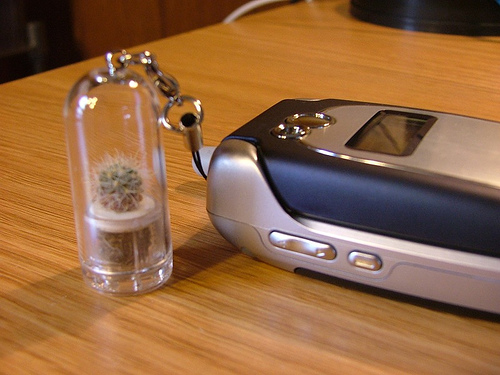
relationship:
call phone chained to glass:
[189, 95, 500, 314] [78, 51, 168, 289]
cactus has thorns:
[89, 159, 145, 214] [83, 126, 159, 202]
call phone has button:
[208, 98, 498, 312] [267, 233, 337, 260]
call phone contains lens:
[189, 95, 500, 314] [273, 104, 342, 143]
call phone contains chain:
[189, 95, 500, 314] [127, 35, 216, 133]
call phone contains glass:
[189, 95, 500, 314] [60, 46, 176, 297]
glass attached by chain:
[60, 46, 176, 297] [127, 35, 216, 133]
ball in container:
[81, 148, 154, 210] [61, 66, 173, 296]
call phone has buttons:
[189, 95, 500, 314] [266, 227, 386, 272]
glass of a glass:
[352, 106, 425, 149] [60, 65, 174, 296]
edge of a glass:
[134, 252, 174, 287] [60, 65, 174, 296]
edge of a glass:
[78, 262, 131, 294] [60, 65, 174, 296]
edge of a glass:
[196, 200, 256, 257] [60, 65, 174, 296]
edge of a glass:
[266, 92, 315, 111] [60, 65, 174, 296]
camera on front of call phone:
[267, 87, 352, 152] [189, 95, 500, 314]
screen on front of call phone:
[338, 95, 449, 191] [189, 95, 500, 314]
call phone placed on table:
[189, 95, 500, 314] [1, 1, 498, 372]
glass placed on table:
[60, 46, 176, 297] [1, 1, 498, 372]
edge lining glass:
[79, 263, 197, 296] [60, 65, 174, 296]